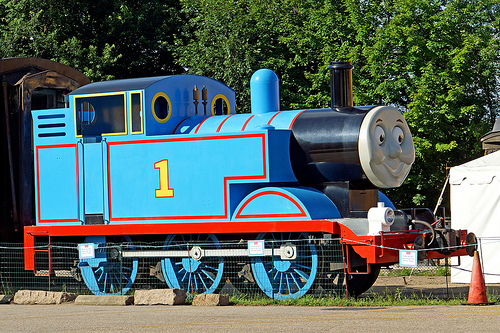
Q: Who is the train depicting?
A: Thomas the Train.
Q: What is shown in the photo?
A: Train.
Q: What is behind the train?
A: Trees.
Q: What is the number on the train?
A: 1.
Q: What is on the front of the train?
A: Face.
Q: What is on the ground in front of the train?
A: Orange cone.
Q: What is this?
A: Train.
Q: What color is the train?
A: Blue.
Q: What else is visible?
A: Tree.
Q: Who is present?
A: No one.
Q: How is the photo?
A: Clear.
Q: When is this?
A: Daytime.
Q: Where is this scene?
A: Amusement park.